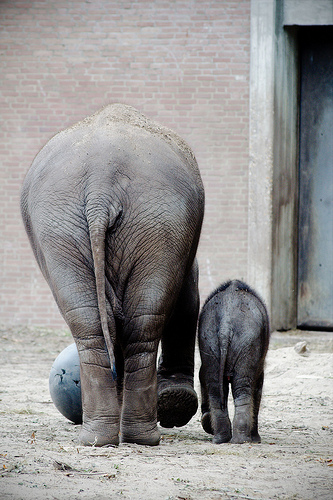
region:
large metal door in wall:
[282, 22, 331, 326]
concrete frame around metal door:
[227, 1, 331, 341]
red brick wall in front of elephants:
[6, 2, 242, 333]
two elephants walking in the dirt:
[1, 101, 331, 497]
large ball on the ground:
[44, 340, 90, 430]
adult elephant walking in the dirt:
[13, 104, 205, 450]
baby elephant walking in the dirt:
[195, 273, 273, 450]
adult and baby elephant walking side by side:
[20, 100, 277, 453]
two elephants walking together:
[16, 97, 281, 450]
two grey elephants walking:
[20, 99, 277, 454]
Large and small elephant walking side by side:
[14, 100, 268, 447]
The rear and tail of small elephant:
[195, 276, 272, 444]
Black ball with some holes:
[47, 334, 120, 425]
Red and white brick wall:
[3, 11, 247, 326]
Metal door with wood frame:
[248, 3, 332, 331]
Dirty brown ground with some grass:
[3, 324, 332, 498]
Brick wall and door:
[2, 3, 332, 354]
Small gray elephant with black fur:
[196, 277, 271, 445]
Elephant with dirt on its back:
[19, 102, 214, 447]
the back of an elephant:
[12, 105, 221, 446]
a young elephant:
[199, 265, 279, 455]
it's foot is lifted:
[143, 346, 209, 438]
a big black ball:
[39, 335, 140, 441]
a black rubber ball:
[27, 334, 134, 428]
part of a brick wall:
[8, 6, 235, 87]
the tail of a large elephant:
[72, 196, 155, 387]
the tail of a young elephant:
[208, 311, 239, 414]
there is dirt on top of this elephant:
[27, 89, 217, 267]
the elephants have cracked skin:
[12, 102, 305, 489]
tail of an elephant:
[205, 323, 238, 414]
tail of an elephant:
[77, 206, 138, 365]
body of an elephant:
[18, 87, 205, 250]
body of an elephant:
[202, 286, 270, 359]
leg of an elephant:
[49, 301, 114, 467]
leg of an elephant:
[126, 303, 174, 439]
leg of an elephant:
[155, 303, 205, 414]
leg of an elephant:
[209, 364, 229, 429]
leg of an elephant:
[233, 370, 263, 438]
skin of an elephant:
[110, 145, 181, 184]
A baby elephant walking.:
[196, 279, 270, 444]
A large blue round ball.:
[48, 344, 117, 425]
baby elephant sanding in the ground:
[193, 280, 268, 442]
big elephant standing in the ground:
[18, 100, 213, 444]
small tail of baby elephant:
[213, 321, 234, 408]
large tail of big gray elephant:
[83, 183, 118, 370]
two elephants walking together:
[19, 100, 267, 452]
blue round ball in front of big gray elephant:
[48, 340, 117, 422]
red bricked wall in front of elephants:
[0, 4, 253, 333]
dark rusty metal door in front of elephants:
[291, 41, 331, 328]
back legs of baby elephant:
[202, 346, 259, 442]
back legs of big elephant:
[32, 208, 165, 449]